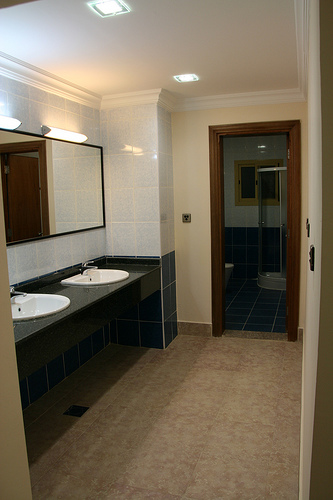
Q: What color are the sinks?
A: White.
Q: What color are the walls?
A: Off white.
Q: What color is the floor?
A: Brown.